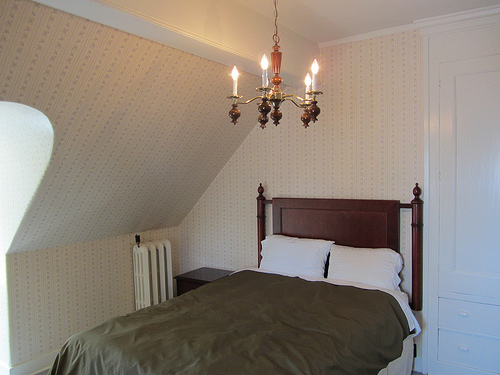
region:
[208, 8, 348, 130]
chandelier hanging over bed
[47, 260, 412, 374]
green blanket on bed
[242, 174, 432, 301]
brown headboard of bed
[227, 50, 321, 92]
four lightbulbs of chandelier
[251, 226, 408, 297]
two white pillows on bed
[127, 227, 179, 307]
white radiator against wall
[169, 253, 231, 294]
dark nightstand next to bed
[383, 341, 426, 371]
white bedskirt of bed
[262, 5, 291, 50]
chain of the chandelier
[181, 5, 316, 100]
light from chandelier on ceiling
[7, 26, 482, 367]
A bedroom in somebody's home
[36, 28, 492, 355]
Somebody's bedroom in a house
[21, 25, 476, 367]
A bed is in a room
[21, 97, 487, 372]
A bed has a brown headboard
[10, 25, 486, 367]
A hanging light is in a room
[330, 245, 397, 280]
A pillow on somebody's bed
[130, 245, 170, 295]
A heater in somebody's room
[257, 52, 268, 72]
A lightbulb on a light fixture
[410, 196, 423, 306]
A post on a bed headboard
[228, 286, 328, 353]
A blanket on somebody's bed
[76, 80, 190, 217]
Wall is white color.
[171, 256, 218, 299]
Side table is brown color.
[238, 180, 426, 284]
Cot is brown color.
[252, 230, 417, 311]
Two pillows are in cot.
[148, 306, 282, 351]
Quilt is brown color.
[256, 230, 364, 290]
Pillows are white color.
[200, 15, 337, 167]
Light is hanging from the ceiling.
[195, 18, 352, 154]
Light is on.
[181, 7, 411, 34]
ceiling is white color.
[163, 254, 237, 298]
Side table is made of wood.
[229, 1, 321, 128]
hanging chandelier turned on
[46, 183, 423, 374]
double bed with dark green sheets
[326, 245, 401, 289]
pillow with white sheet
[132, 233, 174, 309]
a white room furnace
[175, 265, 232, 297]
brown stained bedside table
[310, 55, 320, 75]
lightbulb for hanging chandelier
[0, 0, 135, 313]
pastel patterned colored wallpaper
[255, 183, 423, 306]
brown headboard for bed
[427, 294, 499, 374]
white pullout storage drawers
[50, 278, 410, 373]
dark green comforter for bed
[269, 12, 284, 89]
A bulb holder in the photo.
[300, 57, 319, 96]
Lighting in the photo.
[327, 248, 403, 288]
White pillows in the photo.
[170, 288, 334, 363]
Green bedsheet in the photo.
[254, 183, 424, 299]
Wooden bed in the picture.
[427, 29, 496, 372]
A white door in the photo.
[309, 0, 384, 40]
A white ceiling in the photo.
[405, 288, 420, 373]
White sheets in the photo.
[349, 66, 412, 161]
A wall in the photo.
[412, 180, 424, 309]
A wooden stand in the photo.